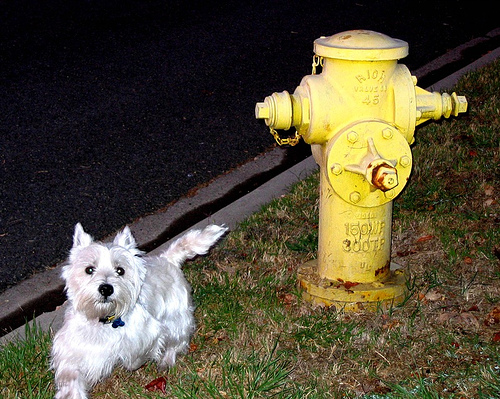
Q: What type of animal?
A: Dog.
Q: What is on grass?
A: Dog.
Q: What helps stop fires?
A: Hydrant.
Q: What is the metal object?
A: Hydrant.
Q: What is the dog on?
A: Grass.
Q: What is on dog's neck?
A: Collar.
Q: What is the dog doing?
A: Looking at the screen.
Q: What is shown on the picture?
A: A white dog and yellow hydrant.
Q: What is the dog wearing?
A: A blue collar.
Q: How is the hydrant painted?
A: Yellow.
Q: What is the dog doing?
A: Looking at the camera.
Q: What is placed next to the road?
A: A yellow hydrant.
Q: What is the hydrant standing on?
A: Grass.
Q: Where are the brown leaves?
A: On the ground.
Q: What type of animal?
A: White dog.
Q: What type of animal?
A: White dog.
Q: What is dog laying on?
A: Grass.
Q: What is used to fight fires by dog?
A: Hydrant.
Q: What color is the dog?
A: White.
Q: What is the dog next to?
A: A fire hydrant.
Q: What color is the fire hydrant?
A: Yellow.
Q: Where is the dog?
A: Near a fire hydrant.